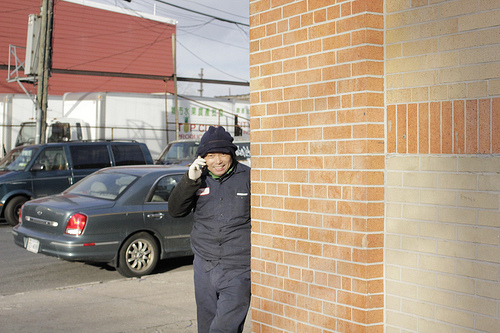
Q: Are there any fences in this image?
A: No, there are no fences.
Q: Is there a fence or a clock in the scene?
A: No, there are no fences or clocks.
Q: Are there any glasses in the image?
A: No, there are no glasses.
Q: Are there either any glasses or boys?
A: No, there are no glasses or boys.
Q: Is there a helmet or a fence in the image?
A: No, there are no fences or helmets.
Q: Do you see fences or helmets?
A: No, there are no fences or helmets.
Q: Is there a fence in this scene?
A: No, there are no fences.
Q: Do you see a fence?
A: No, there are no fences.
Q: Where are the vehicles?
A: The vehicles are on the road.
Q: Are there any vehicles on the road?
A: Yes, there are vehicles on the road.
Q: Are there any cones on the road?
A: No, there are vehicles on the road.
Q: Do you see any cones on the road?
A: No, there are vehicles on the road.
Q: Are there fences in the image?
A: No, there are no fences.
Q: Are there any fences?
A: No, there are no fences.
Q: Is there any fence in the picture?
A: No, there are no fences.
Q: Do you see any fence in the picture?
A: No, there are no fences.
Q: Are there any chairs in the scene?
A: No, there are no chairs.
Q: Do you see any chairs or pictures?
A: No, there are no chairs or pictures.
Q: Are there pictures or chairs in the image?
A: No, there are no chairs or pictures.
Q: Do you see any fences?
A: No, there are no fences.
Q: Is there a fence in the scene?
A: No, there are no fences.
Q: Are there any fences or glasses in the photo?
A: No, there are no fences or glasses.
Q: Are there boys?
A: No, there are no boys.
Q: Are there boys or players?
A: No, there are no boys or players.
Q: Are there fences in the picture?
A: No, there are no fences.